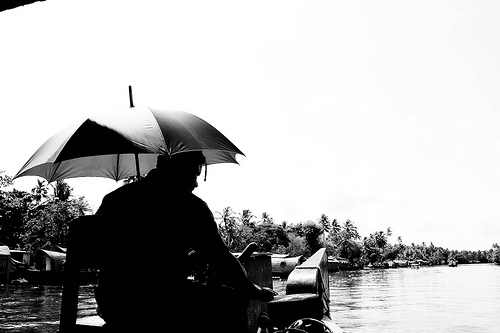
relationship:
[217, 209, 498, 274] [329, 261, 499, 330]
houses along water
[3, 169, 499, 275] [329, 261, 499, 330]
trees growing along water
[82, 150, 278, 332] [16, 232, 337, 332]
man sitting on a boat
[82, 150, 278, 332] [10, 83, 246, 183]
man sitting under umbrella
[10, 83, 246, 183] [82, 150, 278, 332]
umbrella shading man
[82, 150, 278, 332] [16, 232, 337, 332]
man sitting on boat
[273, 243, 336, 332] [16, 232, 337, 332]
front of boat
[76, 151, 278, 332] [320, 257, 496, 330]
person next to river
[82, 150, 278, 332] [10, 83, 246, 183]
man under umbrella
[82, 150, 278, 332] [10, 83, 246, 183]
man holding umbrella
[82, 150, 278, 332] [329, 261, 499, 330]
man looking at water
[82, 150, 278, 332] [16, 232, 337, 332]
man on boat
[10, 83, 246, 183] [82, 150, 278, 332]
umbrella over man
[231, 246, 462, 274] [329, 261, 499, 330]
homes along water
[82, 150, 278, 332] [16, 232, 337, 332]
man riding on boat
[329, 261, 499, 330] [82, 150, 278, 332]
water near man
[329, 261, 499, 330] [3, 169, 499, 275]
water near trees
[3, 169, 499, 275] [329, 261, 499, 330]
trees by water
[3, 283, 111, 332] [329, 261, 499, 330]
ripples in water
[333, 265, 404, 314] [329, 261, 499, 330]
reflections on water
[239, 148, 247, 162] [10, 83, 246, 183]
spoke on umbrella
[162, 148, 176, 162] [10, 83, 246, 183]
spoke on umbrella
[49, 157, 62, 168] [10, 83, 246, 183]
spoke on umbrella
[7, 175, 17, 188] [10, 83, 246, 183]
spoke on umbrella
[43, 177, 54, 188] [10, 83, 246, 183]
spoke on umbrella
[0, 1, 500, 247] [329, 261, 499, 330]
sky above water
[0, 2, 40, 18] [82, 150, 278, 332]
building behind man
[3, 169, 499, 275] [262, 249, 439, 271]
trees by buildings